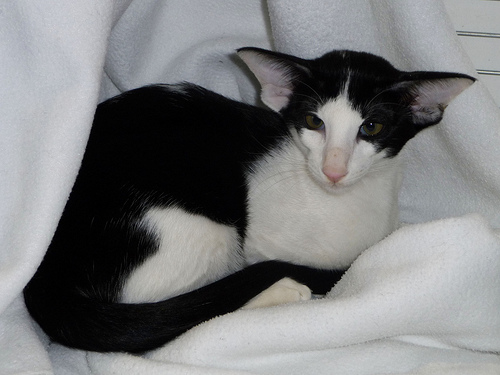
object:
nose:
[321, 155, 350, 182]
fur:
[259, 195, 316, 245]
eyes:
[295, 110, 327, 131]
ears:
[397, 70, 478, 133]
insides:
[260, 68, 282, 96]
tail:
[56, 258, 351, 353]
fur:
[113, 115, 231, 166]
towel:
[384, 253, 499, 342]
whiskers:
[241, 137, 322, 195]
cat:
[23, 46, 479, 354]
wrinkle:
[299, 333, 485, 353]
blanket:
[77, 212, 499, 374]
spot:
[159, 83, 192, 95]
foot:
[244, 275, 312, 309]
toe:
[285, 283, 313, 305]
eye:
[357, 110, 393, 139]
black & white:
[229, 148, 271, 232]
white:
[390, 322, 459, 358]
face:
[283, 76, 403, 195]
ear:
[234, 46, 312, 120]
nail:
[306, 279, 318, 295]